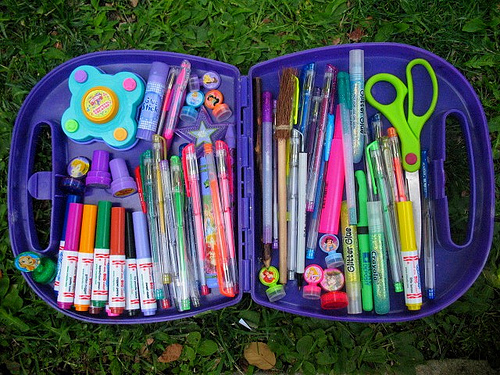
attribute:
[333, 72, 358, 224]
pen — blue